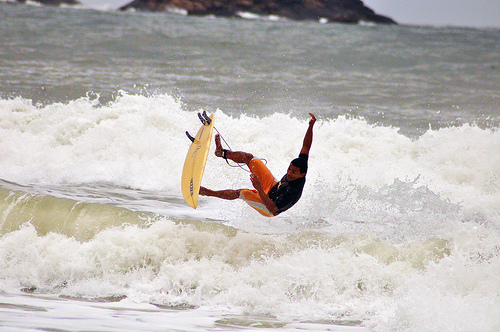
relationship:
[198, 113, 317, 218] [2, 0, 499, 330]
guy surfing in ocean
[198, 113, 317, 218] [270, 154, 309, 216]
guy wearing shirt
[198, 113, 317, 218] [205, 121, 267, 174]
guy with rope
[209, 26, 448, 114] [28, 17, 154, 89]
water in ocean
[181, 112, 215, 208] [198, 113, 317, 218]
board strapped to guy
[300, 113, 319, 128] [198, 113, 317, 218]
hand of guy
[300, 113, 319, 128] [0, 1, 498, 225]
hand in air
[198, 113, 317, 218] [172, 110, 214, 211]
guy has hair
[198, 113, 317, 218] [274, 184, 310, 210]
guy wearing shirt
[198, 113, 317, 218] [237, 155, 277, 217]
guy wearing orange shorts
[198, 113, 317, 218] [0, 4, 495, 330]
guy surfing in water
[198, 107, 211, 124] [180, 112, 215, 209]
fin on bottom of board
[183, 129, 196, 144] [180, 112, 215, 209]
fin on bottom of board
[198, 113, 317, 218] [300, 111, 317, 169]
guy with arm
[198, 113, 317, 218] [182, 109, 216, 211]
guy on board